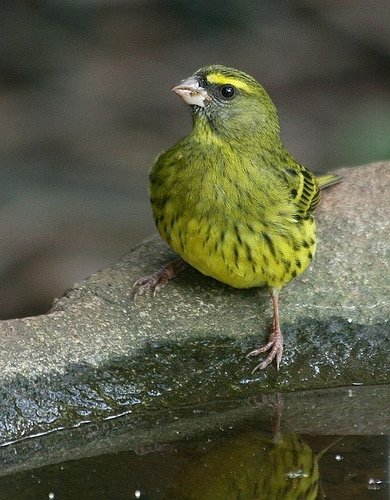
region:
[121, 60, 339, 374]
"A little bird"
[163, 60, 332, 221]
"The bird has yellow mark over his eye"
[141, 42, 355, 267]
"Little bird is looking up"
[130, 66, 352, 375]
"The bird is perched on a rock"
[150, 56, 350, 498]
"The bird is perched near some water"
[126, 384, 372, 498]
"The bird's reflection in the water"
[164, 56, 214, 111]
"A picture of the bird's beak"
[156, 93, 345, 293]
"The bird is covered in feathers"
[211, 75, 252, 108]
"A picture of the bird's eye"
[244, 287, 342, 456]
"The bird's foot is very close to the water"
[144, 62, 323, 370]
this is a bird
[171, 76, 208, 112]
this is the beak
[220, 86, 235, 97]
this is the bird's eye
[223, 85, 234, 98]
the eye is black in color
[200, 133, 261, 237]
the feathers are green in color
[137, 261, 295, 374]
these are the bird's feet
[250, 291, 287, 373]
the foot is stretched out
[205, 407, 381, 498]
this is a water pond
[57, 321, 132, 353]
this is a stone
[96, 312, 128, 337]
the stone is grey in color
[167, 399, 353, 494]
reflection of the bird in the water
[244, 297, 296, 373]
pink and grey toned bird foot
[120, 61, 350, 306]
yellow, green, and black bird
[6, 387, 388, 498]
small body of water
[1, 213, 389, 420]
gray rock formation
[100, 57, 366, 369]
bird standing on a rock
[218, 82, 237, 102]
tiny, round, black eye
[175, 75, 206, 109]
sharp white beak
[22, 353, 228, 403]
wet spots on the rock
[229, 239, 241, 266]
black stripe on the yellowish fur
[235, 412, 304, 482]
Dark colored water.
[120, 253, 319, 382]
A small birds feet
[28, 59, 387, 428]
A bird by the water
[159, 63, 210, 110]
A small birds beak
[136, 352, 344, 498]
A reflection of the bird in the water.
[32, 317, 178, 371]
A grey stone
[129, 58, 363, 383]
A small yellow and black bird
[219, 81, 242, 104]
A small black bird eye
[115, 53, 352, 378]
A bird standing on a bird bath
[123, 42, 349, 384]
A bird looking away from the camera.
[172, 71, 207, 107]
the beak of a bird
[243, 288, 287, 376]
the talon of a bird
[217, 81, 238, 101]
the black eye of a bird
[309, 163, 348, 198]
the tail of a bird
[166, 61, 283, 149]
the head of a bird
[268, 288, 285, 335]
the leg of a bird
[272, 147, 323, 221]
the wing of a bird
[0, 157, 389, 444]
a gray cement ledge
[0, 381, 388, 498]
a small pond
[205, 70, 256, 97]
a yellow stripe over the eye